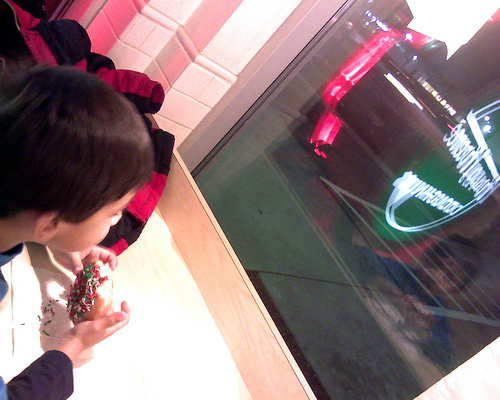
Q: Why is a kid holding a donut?
A: Kid is eating donut.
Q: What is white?
A: Countertop.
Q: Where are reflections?
A: On the window.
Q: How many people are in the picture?
A: One.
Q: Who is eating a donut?
A: A boy.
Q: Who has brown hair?
A: Little boy.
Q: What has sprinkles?
A: The donut.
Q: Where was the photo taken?
A: In the diner.